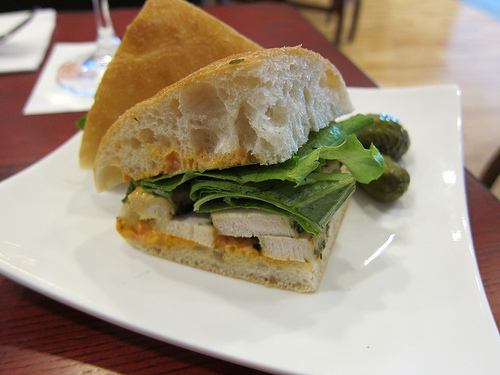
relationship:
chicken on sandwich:
[215, 210, 297, 237] [71, 5, 408, 295]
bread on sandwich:
[86, 0, 351, 180] [169, 44, 344, 200]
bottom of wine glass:
[54, 38, 124, 99] [61, 3, 137, 101]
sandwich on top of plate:
[71, 5, 408, 295] [0, 82, 499, 373]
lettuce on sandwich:
[313, 113, 386, 186] [56, 8, 439, 313]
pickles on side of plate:
[332, 109, 409, 206] [0, 82, 499, 373]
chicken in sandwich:
[215, 210, 297, 237] [71, 5, 408, 295]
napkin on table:
[43, 44, 103, 124] [51, 7, 377, 151]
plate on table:
[0, 46, 494, 373] [0, 1, 499, 373]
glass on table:
[58, 0, 134, 109] [0, 1, 499, 373]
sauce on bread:
[118, 212, 195, 249] [86, 0, 351, 180]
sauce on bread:
[118, 212, 195, 249] [113, 202, 355, 285]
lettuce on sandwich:
[142, 124, 378, 229] [89, 43, 357, 298]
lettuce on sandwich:
[277, 142, 332, 201] [88, 45, 385, 292]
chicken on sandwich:
[129, 191, 184, 224] [71, 5, 408, 295]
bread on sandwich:
[118, 201, 357, 295] [88, 45, 385, 292]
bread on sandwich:
[96, 44, 350, 200] [90, 10, 344, 300]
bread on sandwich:
[119, 201, 356, 295] [71, 5, 408, 295]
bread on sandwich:
[86, 0, 351, 180] [71, 5, 408, 295]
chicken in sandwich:
[160, 211, 312, 261] [77, 0, 360, 294]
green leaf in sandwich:
[214, 169, 359, 233] [77, 0, 360, 294]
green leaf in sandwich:
[214, 169, 359, 233] [101, 45, 420, 287]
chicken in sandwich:
[160, 211, 312, 261] [101, 45, 420, 287]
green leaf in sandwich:
[214, 121, 384, 241] [71, 5, 408, 295]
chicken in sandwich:
[129, 191, 314, 278] [71, 5, 408, 295]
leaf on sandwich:
[120, 110, 386, 231] [98, 34, 413, 279]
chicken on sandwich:
[215, 210, 297, 237] [98, 34, 413, 279]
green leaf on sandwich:
[214, 169, 359, 233] [71, 5, 408, 295]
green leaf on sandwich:
[214, 169, 359, 233] [77, 0, 360, 294]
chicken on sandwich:
[129, 191, 184, 224] [77, 0, 360, 294]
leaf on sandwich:
[120, 110, 386, 231] [121, 115, 398, 255]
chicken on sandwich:
[215, 210, 297, 237] [121, 115, 398, 255]